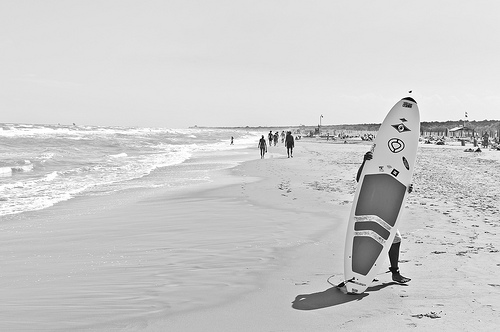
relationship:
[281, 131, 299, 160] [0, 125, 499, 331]
people on beach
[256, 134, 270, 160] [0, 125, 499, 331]
people on beach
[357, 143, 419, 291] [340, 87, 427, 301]
person carrying surfboard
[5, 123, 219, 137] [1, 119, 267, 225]
waves in ocean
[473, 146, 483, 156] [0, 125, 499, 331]
people on beach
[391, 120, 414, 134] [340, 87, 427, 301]
markings on surfboard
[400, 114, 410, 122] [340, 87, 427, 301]
markings on surfboard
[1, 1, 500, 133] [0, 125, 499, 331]
sky over beach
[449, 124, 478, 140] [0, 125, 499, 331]
building on beach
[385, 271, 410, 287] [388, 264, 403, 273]
foot with bracelet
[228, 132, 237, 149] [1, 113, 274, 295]
child on shoreline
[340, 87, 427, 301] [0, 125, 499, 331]
surfboard on beach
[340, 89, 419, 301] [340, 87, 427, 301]
surfboard on surfboard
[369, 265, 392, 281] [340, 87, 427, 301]
leash from surfboard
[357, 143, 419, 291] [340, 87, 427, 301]
person holding surfboard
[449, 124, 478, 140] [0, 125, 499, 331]
building by beach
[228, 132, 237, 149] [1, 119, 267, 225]
child in ocean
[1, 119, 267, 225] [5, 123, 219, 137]
ocean has waves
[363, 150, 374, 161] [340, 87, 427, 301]
hand on surfboard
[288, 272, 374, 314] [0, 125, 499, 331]
shadow in beach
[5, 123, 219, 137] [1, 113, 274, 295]
waves crashing to shoreline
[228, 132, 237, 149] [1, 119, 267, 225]
child toward ocean